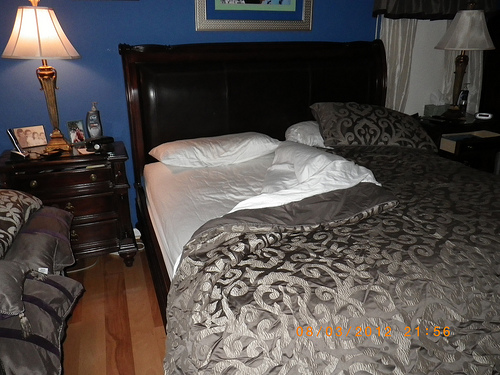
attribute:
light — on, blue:
[0, 0, 82, 152]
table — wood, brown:
[1, 140, 139, 267]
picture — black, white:
[7, 125, 49, 150]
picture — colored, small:
[65, 119, 86, 142]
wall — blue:
[1, 0, 379, 225]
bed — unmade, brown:
[115, 38, 498, 373]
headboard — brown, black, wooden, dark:
[118, 38, 386, 179]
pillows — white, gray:
[145, 99, 440, 170]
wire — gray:
[64, 240, 145, 273]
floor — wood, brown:
[63, 239, 176, 374]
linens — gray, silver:
[161, 146, 500, 373]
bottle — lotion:
[87, 101, 104, 142]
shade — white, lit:
[1, 2, 80, 63]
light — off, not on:
[433, 9, 494, 115]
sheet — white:
[142, 147, 383, 281]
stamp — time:
[296, 323, 452, 340]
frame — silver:
[192, 1, 313, 32]